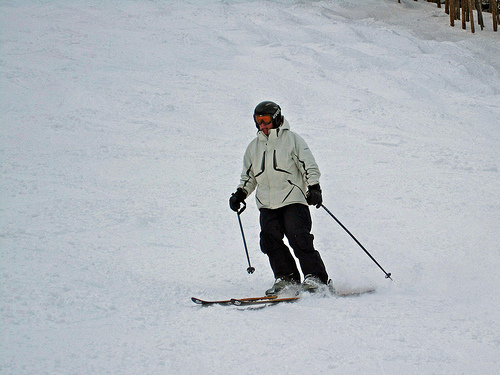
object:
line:
[287, 180, 306, 199]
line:
[282, 185, 296, 203]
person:
[228, 100, 330, 295]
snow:
[117, 317, 207, 372]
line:
[242, 163, 252, 188]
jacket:
[236, 115, 321, 210]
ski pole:
[236, 202, 255, 274]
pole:
[320, 203, 393, 281]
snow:
[399, 290, 492, 339]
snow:
[88, 71, 213, 185]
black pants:
[258, 202, 328, 285]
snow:
[10, 304, 55, 331]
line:
[293, 152, 309, 184]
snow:
[433, 262, 495, 287]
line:
[254, 151, 265, 178]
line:
[272, 149, 292, 174]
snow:
[0, 0, 140, 62]